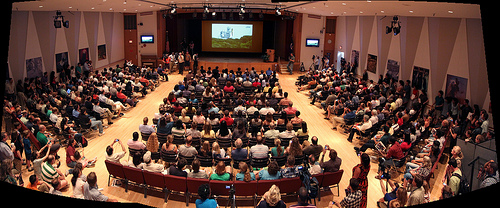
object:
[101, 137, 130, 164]
man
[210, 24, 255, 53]
television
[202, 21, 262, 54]
wall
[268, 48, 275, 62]
podium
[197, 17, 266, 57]
screen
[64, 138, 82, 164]
woman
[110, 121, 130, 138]
floor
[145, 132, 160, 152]
hair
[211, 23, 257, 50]
image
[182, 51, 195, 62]
people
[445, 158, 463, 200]
man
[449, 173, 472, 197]
black backpack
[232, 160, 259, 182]
woman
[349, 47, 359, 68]
painting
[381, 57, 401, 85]
painting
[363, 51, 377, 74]
painting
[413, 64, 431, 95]
painting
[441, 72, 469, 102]
painting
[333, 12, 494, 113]
wall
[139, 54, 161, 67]
piano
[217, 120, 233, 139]
people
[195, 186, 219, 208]
woman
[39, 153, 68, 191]
man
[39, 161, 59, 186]
shirt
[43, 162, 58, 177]
stripe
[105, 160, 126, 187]
seats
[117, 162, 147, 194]
seats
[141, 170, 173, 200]
seats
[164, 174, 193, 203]
seats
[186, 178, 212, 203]
seats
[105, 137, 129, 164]
people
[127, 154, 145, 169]
people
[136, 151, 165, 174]
people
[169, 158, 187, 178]
people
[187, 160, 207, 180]
people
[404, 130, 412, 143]
black haired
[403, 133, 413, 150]
woman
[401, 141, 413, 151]
red shirt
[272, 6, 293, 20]
light fixture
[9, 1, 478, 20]
ceiling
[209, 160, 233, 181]
people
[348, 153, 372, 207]
woman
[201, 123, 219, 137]
woman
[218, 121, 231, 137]
hair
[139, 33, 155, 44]
screens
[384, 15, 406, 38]
light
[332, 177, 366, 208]
man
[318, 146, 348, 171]
man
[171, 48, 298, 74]
stage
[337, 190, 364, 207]
shirt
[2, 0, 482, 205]
large auditorium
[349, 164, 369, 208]
dress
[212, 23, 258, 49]
film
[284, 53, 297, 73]
person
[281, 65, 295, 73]
stairs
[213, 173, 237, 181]
shirt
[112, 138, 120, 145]
camera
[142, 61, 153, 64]
bench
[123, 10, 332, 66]
wall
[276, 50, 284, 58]
plant